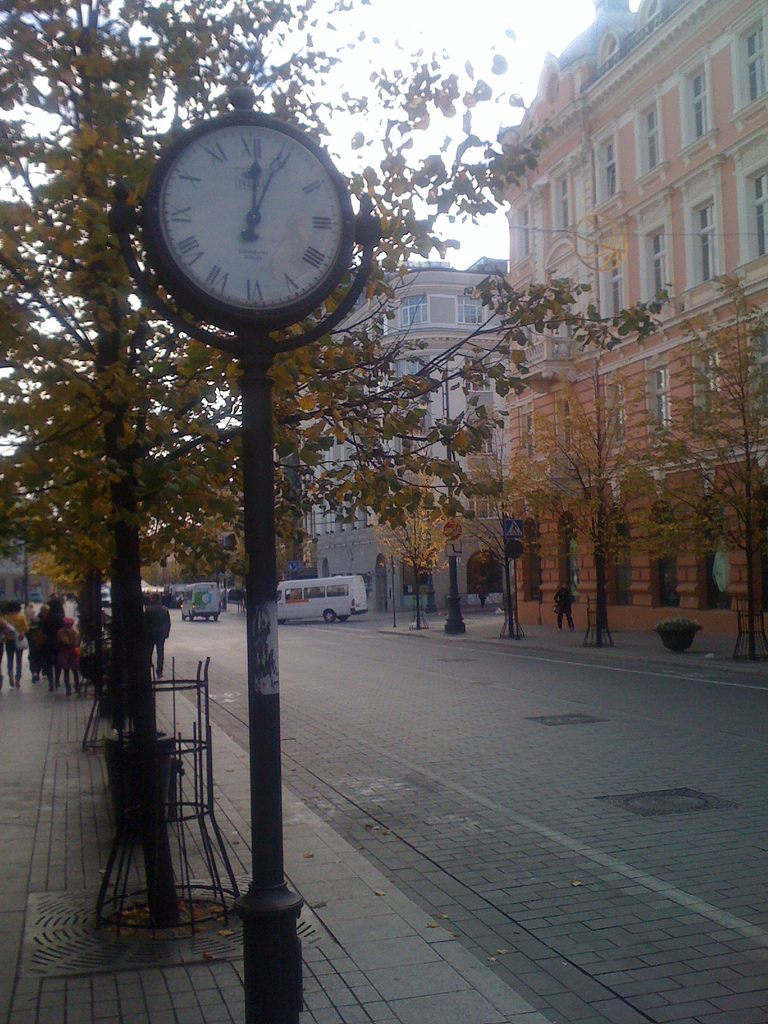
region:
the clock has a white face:
[148, 10, 395, 335]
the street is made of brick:
[402, 645, 722, 970]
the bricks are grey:
[472, 641, 747, 981]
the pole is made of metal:
[199, 332, 324, 1008]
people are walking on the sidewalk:
[9, 544, 125, 752]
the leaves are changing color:
[130, 274, 498, 599]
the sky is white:
[389, 5, 566, 254]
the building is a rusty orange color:
[462, 354, 741, 656]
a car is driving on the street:
[238, 541, 389, 658]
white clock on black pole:
[103, 82, 390, 855]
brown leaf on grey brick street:
[557, 869, 594, 900]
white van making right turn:
[261, 567, 371, 632]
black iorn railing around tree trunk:
[79, 631, 243, 948]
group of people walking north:
[0, 591, 86, 701]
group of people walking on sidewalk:
[6, 579, 88, 695]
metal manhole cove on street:
[595, 770, 742, 823]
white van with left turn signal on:
[177, 576, 229, 618]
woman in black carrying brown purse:
[551, 576, 581, 637]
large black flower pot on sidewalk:
[643, 611, 711, 661]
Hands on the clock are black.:
[221, 140, 306, 273]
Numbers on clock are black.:
[151, 115, 335, 310]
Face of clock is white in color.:
[176, 105, 344, 333]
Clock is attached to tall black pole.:
[179, 337, 332, 909]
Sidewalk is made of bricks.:
[36, 742, 456, 1021]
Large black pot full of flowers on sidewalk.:
[640, 601, 718, 670]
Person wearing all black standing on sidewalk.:
[545, 574, 582, 640]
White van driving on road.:
[252, 575, 389, 630]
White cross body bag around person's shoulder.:
[4, 612, 32, 666]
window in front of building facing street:
[518, 202, 531, 258]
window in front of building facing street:
[557, 172, 572, 233]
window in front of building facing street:
[599, 132, 618, 199]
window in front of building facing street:
[687, 67, 706, 141]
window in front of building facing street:
[743, 25, 766, 103]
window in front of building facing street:
[603, 250, 624, 321]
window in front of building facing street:
[653, 365, 673, 434]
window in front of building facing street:
[612, 379, 627, 446]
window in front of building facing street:
[750, 163, 765, 263]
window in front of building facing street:
[694, 193, 723, 283]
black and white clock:
[157, 113, 341, 322]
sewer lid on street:
[623, 792, 708, 820]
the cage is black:
[95, 662, 245, 925]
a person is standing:
[54, 616, 80, 697]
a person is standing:
[3, 603, 28, 690]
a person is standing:
[142, 594, 168, 674]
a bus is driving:
[269, 577, 366, 623]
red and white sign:
[445, 515, 462, 540]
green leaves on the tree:
[408, 374, 473, 444]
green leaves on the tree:
[204, 497, 241, 543]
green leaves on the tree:
[157, 435, 198, 498]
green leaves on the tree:
[63, 503, 95, 579]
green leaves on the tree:
[401, 424, 438, 476]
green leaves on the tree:
[691, 508, 732, 584]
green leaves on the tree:
[555, 486, 616, 567]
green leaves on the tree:
[78, 10, 121, 218]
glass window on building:
[733, 154, 765, 260]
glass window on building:
[685, 188, 716, 280]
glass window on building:
[644, 214, 664, 299]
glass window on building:
[605, 253, 622, 324]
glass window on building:
[512, 200, 535, 261]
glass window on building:
[552, 173, 572, 232]